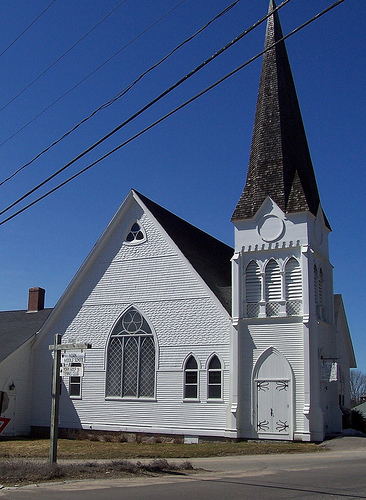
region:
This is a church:
[23, 203, 302, 410]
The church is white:
[143, 298, 247, 419]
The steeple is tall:
[186, 26, 363, 292]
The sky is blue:
[19, 39, 218, 165]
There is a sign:
[33, 343, 126, 495]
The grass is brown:
[100, 447, 248, 495]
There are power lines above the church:
[18, 30, 220, 188]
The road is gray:
[206, 441, 272, 495]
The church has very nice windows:
[89, 320, 262, 473]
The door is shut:
[248, 378, 355, 471]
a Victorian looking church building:
[0, 2, 361, 442]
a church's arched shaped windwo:
[96, 299, 153, 398]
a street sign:
[45, 330, 92, 469]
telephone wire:
[21, 10, 215, 183]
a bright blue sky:
[144, 128, 229, 199]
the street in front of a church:
[120, 470, 362, 497]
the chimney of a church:
[27, 286, 46, 313]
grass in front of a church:
[69, 439, 277, 453]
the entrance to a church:
[249, 345, 298, 443]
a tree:
[346, 370, 363, 401]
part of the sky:
[306, 69, 327, 108]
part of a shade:
[231, 466, 263, 492]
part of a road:
[194, 485, 213, 498]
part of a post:
[41, 431, 64, 468]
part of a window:
[202, 364, 226, 402]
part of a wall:
[181, 397, 206, 416]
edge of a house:
[294, 389, 329, 435]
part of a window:
[117, 361, 143, 385]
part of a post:
[33, 387, 64, 424]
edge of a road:
[133, 470, 159, 488]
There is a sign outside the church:
[33, 328, 102, 497]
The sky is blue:
[80, 35, 317, 215]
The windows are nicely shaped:
[101, 302, 269, 437]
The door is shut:
[240, 348, 308, 453]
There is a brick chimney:
[8, 268, 84, 327]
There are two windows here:
[172, 350, 261, 425]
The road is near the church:
[138, 453, 272, 497]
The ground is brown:
[31, 435, 142, 499]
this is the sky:
[309, 31, 363, 134]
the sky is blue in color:
[177, 127, 215, 184]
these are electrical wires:
[91, 63, 192, 113]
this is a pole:
[46, 339, 57, 457]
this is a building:
[96, 248, 199, 431]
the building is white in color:
[143, 275, 181, 314]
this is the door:
[254, 381, 295, 442]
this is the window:
[183, 371, 195, 399]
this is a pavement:
[270, 455, 350, 496]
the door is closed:
[253, 380, 290, 430]